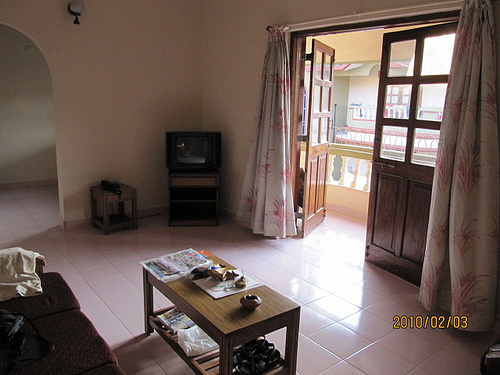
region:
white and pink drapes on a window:
[239, 0, 499, 335]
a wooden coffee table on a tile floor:
[141, 245, 301, 372]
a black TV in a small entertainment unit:
[165, 128, 220, 172]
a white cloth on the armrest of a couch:
[2, 245, 42, 300]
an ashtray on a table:
[241, 292, 262, 309]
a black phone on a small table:
[98, 177, 122, 201]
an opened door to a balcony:
[302, 33, 335, 233]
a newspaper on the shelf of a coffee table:
[152, 305, 194, 335]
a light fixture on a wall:
[68, 0, 84, 26]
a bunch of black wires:
[234, 333, 281, 374]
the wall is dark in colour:
[77, 50, 193, 122]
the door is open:
[291, 28, 381, 242]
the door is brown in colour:
[371, 185, 418, 242]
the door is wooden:
[370, 174, 429, 275]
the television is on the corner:
[164, 129, 231, 169]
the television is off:
[146, 129, 231, 172]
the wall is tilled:
[292, 225, 343, 317]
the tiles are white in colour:
[271, 230, 346, 282]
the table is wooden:
[143, 244, 297, 371]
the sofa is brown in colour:
[15, 263, 93, 370]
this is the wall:
[92, 40, 191, 116]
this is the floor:
[307, 239, 379, 318]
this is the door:
[307, 35, 339, 229]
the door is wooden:
[310, 75, 329, 202]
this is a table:
[193, 303, 262, 362]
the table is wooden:
[208, 311, 256, 338]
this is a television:
[163, 130, 218, 172]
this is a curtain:
[258, 37, 298, 227]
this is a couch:
[48, 294, 98, 372]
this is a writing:
[381, 309, 472, 329]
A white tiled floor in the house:
[294, 255, 330, 287]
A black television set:
[166, 125, 223, 170]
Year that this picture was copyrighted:
[388, 313, 424, 332]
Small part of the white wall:
[88, 94, 108, 114]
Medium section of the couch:
[53, 310, 105, 367]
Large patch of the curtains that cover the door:
[453, 147, 491, 295]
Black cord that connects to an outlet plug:
[146, 212, 161, 222]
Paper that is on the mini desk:
[148, 249, 206, 280]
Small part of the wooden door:
[380, 176, 409, 231]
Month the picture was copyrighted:
[429, 309, 444, 333]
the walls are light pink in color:
[118, 9, 199, 91]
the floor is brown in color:
[356, 293, 471, 366]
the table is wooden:
[228, 309, 324, 371]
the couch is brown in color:
[33, 310, 99, 374]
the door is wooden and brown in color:
[378, 165, 431, 269]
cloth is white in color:
[8, 245, 39, 290]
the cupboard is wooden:
[168, 122, 220, 226]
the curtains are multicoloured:
[250, 54, 293, 193]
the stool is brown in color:
[86, 175, 143, 225]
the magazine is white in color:
[160, 248, 207, 276]